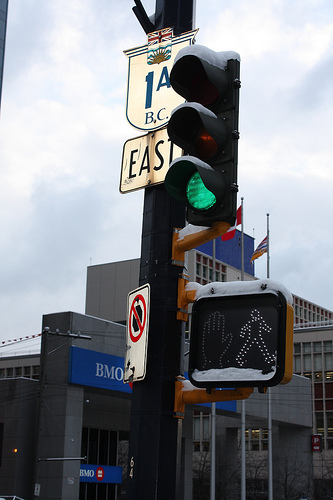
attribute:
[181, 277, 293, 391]
sign — no walking, walking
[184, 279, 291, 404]
sign — pedestrian walking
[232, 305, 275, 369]
image — lighted, of pedestrian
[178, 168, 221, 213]
light — green, traffic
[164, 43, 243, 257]
sign — signal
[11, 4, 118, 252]
sky — cloudy, in distance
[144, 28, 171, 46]
flag — british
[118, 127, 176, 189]
sign — direction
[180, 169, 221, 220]
signal — green, on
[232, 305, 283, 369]
signal — man walking, lit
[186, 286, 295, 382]
light — guiding traffic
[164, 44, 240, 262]
signal — traffic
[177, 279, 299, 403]
signal — traffic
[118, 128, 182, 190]
direction sign — on pole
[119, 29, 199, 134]
street sign — on pole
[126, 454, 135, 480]
number 64 — on pole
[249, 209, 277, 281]
flag — on top of building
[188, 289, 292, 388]
sign — street crossing, covered in snow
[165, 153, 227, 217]
lowest light — shining green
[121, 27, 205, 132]
roadway sign — British Columbia, indicating 1A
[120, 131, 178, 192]
direction sign — white, rectangular, reading EAST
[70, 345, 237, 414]
business sign — long, blue, displaying letters BMO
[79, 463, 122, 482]
business sign — blue, small, displaying letters BMO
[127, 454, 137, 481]
white number — 64, on black traffic signal pole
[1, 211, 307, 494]
multi-story building — large, constructed of concrete, metal and glass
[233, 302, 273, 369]
outline — of a walking person, on traffic signal 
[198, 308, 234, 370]
hand outline — on a traffic signal 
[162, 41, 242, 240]
street light — big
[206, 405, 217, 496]
grey pole — skinny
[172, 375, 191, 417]
street light — pole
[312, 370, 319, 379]
window — very small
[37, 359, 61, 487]
grey wall — big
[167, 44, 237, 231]
traffic light — with green lit up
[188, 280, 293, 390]
crossing sign — with walking figure lit up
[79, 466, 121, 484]
blue sign — with BMO in white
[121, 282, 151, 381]
sign — white, no stop sign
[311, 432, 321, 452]
red sign — with a white p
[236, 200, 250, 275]
pole — silver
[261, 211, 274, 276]
pole — silver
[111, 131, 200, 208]
sign — white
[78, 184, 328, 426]
building — large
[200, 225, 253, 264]
accent — blue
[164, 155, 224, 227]
light — green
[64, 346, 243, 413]
sign — blue, white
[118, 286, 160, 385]
sign — white, black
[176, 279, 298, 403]
crosswalk sign — black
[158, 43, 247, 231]
traffic light — black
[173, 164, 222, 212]
traffic light — green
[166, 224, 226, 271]
arm — yellow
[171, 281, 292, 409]
trim — yellow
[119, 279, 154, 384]
sign — red, white, black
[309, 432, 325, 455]
parking sign — red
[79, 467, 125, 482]
sign — blue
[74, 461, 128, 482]
sign — blue, red, white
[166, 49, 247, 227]
traffic light — green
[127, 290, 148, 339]
cross out — red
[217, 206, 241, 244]
flag — red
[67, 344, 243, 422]
company sign — blue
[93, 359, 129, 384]
letters — white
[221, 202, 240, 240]
flag — tall